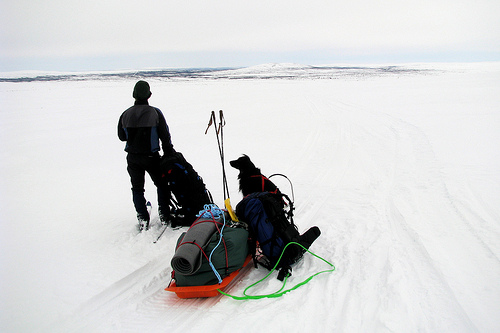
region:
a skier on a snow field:
[108, 65, 192, 236]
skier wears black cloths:
[111, 68, 179, 235]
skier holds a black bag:
[116, 70, 215, 222]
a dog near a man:
[226, 150, 302, 229]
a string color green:
[222, 233, 339, 310]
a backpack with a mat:
[159, 183, 253, 288]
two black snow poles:
[201, 103, 238, 216]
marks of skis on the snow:
[320, 184, 497, 331]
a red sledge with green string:
[163, 270, 302, 305]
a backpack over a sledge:
[159, 195, 249, 306]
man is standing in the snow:
[66, 52, 376, 308]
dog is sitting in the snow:
[195, 136, 325, 236]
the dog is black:
[211, 142, 291, 210]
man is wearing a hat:
[121, 68, 176, 115]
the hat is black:
[93, 62, 171, 113]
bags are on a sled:
[150, 204, 289, 302]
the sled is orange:
[154, 228, 256, 312]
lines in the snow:
[77, 256, 357, 320]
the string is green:
[211, 233, 339, 313]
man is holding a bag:
[112, 87, 206, 198]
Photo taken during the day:
[5, 3, 495, 323]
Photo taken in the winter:
[10, 11, 490, 321]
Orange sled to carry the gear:
[160, 217, 280, 314]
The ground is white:
[5, 47, 497, 327]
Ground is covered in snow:
[25, 47, 486, 325]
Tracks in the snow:
[101, 245, 295, 327]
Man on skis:
[108, 65, 173, 249]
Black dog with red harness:
[231, 138, 311, 235]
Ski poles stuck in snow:
[194, 100, 247, 224]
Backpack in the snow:
[147, 143, 227, 220]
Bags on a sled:
[176, 195, 251, 283]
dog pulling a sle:
[232, 150, 277, 204]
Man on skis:
[121, 178, 171, 245]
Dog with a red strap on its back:
[249, 168, 278, 192]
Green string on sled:
[223, 264, 323, 298]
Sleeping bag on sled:
[167, 215, 210, 287]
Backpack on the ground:
[231, 183, 314, 265]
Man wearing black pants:
[120, 149, 175, 229]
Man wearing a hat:
[129, 80, 154, 97]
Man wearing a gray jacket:
[117, 105, 168, 158]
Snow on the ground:
[351, 301, 381, 330]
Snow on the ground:
[400, 296, 440, 324]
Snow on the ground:
[413, 222, 440, 282]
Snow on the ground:
[21, 277, 56, 317]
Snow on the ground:
[28, 131, 61, 184]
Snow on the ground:
[324, 86, 394, 148]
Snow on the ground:
[398, 98, 437, 154]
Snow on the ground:
[277, 102, 345, 165]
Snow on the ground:
[32, 136, 144, 213]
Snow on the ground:
[107, 235, 219, 268]